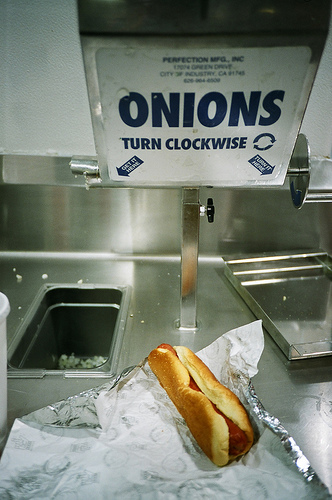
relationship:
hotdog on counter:
[147, 335, 262, 467] [5, 333, 331, 497]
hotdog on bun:
[155, 335, 250, 467] [139, 344, 194, 396]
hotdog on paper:
[147, 335, 262, 467] [21, 374, 187, 494]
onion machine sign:
[105, 80, 264, 142] [82, 21, 306, 194]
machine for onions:
[65, 0, 325, 301] [106, 79, 296, 139]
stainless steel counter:
[11, 212, 173, 288] [5, 333, 331, 497]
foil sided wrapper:
[255, 398, 321, 482] [220, 315, 319, 499]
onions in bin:
[57, 340, 109, 369] [29, 273, 129, 383]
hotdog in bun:
[147, 335, 262, 467] [139, 344, 194, 396]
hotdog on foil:
[147, 335, 262, 467] [255, 398, 321, 482]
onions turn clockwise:
[106, 79, 296, 139] [160, 129, 280, 161]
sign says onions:
[82, 21, 306, 194] [106, 79, 296, 139]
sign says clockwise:
[82, 21, 306, 194] [160, 129, 280, 161]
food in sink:
[11, 267, 117, 380] [29, 273, 129, 383]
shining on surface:
[66, 228, 157, 284] [9, 234, 151, 281]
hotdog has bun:
[147, 335, 262, 467] [139, 344, 194, 396]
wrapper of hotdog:
[220, 315, 319, 499] [147, 335, 262, 467]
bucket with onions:
[29, 273, 129, 383] [57, 340, 109, 369]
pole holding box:
[173, 177, 223, 335] [73, 16, 309, 191]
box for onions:
[73, 16, 309, 191] [106, 79, 296, 139]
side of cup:
[0, 284, 32, 473] [0, 280, 29, 466]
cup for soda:
[0, 280, 29, 466] [0, 279, 26, 475]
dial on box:
[195, 193, 231, 238] [73, 16, 309, 191]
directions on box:
[109, 125, 280, 159] [73, 16, 309, 191]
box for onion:
[73, 16, 309, 191] [105, 80, 264, 142]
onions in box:
[106, 79, 296, 139] [73, 16, 309, 191]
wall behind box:
[6, 2, 113, 152] [73, 16, 309, 191]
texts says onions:
[106, 45, 284, 183] [106, 79, 296, 139]